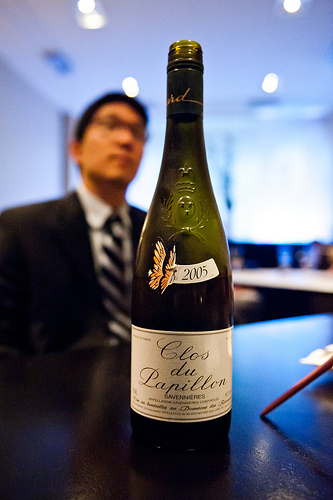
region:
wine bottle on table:
[128, 53, 234, 473]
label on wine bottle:
[123, 312, 233, 431]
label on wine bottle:
[142, 243, 229, 298]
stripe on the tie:
[100, 278, 121, 297]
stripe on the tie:
[102, 238, 121, 262]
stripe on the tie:
[100, 303, 115, 321]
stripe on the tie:
[101, 316, 134, 342]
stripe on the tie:
[105, 234, 123, 254]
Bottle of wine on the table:
[137, 34, 235, 454]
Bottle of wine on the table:
[120, 316, 245, 456]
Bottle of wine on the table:
[101, 204, 262, 439]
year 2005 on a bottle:
[148, 241, 219, 283]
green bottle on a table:
[117, 226, 256, 485]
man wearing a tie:
[89, 208, 137, 304]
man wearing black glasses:
[90, 108, 157, 150]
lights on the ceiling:
[240, 62, 279, 98]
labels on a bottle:
[128, 310, 235, 420]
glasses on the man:
[85, 112, 145, 133]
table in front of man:
[8, 417, 326, 493]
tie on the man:
[96, 199, 132, 339]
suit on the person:
[4, 199, 136, 316]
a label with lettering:
[128, 328, 241, 420]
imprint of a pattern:
[155, 165, 213, 240]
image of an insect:
[145, 229, 179, 294]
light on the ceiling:
[246, 68, 282, 89]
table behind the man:
[233, 256, 332, 301]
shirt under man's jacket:
[76, 180, 136, 329]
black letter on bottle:
[186, 337, 199, 351]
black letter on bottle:
[136, 366, 163, 398]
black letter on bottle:
[160, 369, 185, 392]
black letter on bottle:
[180, 378, 207, 400]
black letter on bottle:
[193, 368, 220, 390]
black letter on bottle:
[198, 372, 220, 382]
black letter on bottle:
[172, 354, 195, 373]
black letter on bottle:
[154, 334, 185, 367]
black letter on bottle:
[185, 333, 223, 369]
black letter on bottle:
[218, 372, 222, 385]